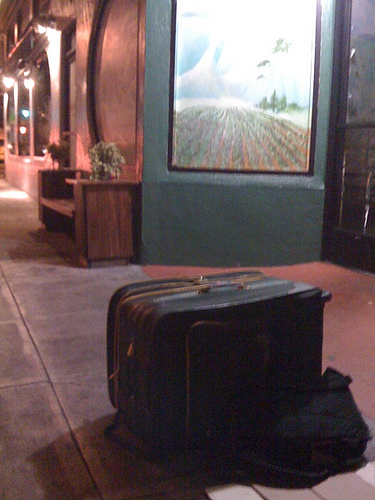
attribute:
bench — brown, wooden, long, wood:
[35, 151, 149, 269]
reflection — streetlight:
[17, 106, 31, 141]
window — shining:
[15, 71, 35, 153]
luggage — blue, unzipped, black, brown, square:
[96, 260, 371, 494]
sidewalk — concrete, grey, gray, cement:
[0, 173, 212, 499]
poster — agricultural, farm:
[163, 0, 324, 180]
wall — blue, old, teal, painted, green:
[141, 0, 326, 271]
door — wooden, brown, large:
[319, 0, 374, 277]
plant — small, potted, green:
[83, 138, 130, 185]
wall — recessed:
[1, 0, 143, 204]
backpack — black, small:
[188, 362, 371, 491]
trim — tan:
[102, 267, 269, 435]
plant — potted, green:
[39, 128, 77, 173]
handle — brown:
[193, 275, 253, 300]